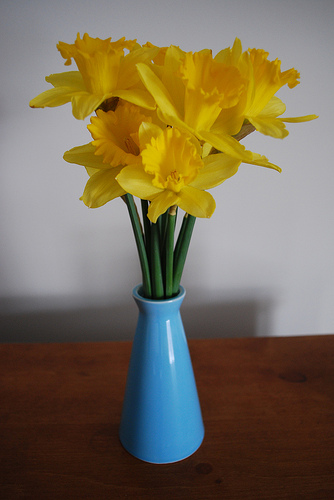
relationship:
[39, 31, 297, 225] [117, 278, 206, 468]
flowers in vase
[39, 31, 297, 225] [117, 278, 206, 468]
flowers in a vase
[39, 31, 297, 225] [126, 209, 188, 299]
flowers has stems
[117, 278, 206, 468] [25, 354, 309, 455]
vase on table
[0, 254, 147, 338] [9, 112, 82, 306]
shadow on wall